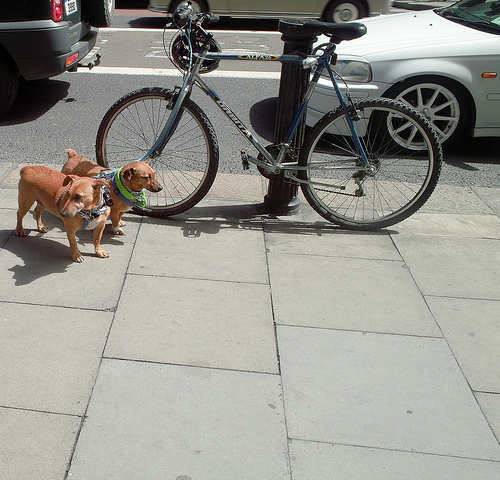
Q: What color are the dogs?
A: Brown.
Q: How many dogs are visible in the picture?
A: Two.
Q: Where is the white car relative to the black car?
A: Behind it.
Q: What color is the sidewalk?
A: Gray.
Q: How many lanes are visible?
A: Three.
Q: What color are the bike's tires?
A: Black.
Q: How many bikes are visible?
A: One.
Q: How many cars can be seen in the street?
A: Three.